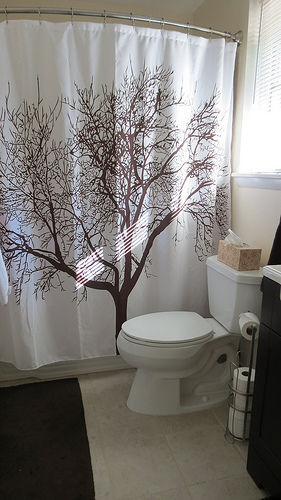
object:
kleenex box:
[217, 239, 262, 271]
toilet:
[117, 254, 265, 417]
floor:
[2, 367, 260, 500]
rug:
[0, 376, 96, 499]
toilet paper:
[233, 367, 255, 395]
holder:
[223, 311, 259, 445]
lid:
[121, 310, 213, 344]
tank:
[205, 254, 266, 337]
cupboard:
[246, 264, 280, 500]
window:
[237, 0, 281, 177]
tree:
[0, 56, 232, 357]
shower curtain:
[0, 19, 237, 371]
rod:
[0, 6, 244, 47]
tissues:
[224, 228, 243, 247]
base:
[117, 310, 240, 416]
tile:
[107, 424, 187, 498]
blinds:
[246, 0, 281, 168]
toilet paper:
[239, 312, 260, 341]